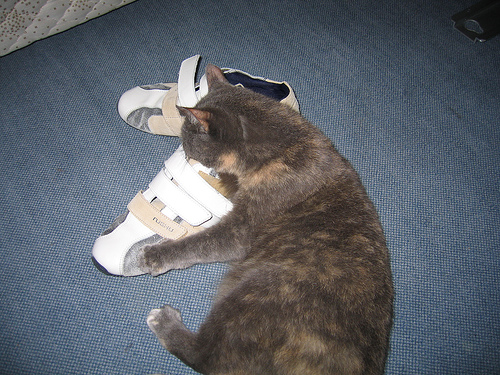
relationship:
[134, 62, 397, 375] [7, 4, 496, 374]
cat laying on ground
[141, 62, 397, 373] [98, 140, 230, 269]
cat looking at shoe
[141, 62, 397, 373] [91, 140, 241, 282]
cat distracted by shoe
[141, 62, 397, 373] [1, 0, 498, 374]
cat sitting on sofa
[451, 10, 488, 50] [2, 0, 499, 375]
metal on carpet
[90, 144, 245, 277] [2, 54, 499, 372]
shoe sitting on sofa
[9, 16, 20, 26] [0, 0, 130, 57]
spots on fabric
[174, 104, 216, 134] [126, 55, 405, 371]
ear of cat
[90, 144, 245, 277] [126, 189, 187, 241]
shoe has strap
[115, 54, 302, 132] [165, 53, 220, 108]
shoe has straps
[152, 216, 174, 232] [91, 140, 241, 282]
writing on shoe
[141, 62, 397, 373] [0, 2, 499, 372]
cat on surface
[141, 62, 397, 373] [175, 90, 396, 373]
cat sniffing shoe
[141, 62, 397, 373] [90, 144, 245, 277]
cat playing with shoe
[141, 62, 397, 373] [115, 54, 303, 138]
cat playing with shoe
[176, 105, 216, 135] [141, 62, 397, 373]
ear of cat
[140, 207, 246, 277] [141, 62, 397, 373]
leg of cat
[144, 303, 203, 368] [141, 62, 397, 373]
leg of cat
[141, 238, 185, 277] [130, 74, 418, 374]
paw of cat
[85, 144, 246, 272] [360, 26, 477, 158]
shoe on ground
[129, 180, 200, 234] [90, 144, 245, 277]
strap on shoe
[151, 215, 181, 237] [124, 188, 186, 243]
writing on strap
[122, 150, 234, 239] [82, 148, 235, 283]
strap on shoe